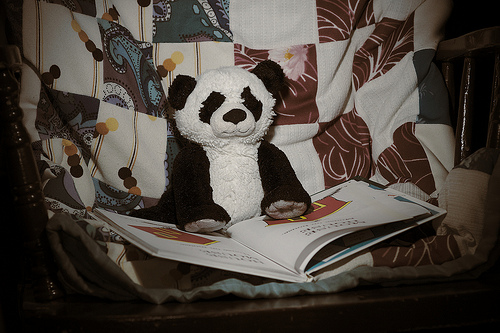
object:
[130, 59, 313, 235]
teddy bear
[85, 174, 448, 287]
book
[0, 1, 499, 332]
chair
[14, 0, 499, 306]
quilt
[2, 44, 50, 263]
arm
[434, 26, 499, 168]
arm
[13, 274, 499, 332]
seat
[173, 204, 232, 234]
hands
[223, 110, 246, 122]
nose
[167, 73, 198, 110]
ear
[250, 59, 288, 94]
ear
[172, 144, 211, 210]
arms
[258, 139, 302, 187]
arms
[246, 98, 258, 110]
eye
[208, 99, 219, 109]
eye